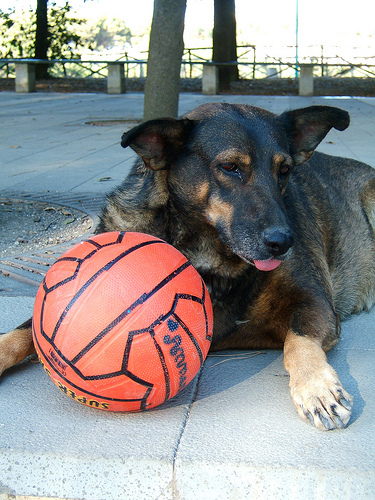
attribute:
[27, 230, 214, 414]
ball — orange, black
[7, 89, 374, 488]
ground — concrete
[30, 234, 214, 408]
lines — black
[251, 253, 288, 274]
tongue — pink, out, sticking out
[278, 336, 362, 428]
dog — laying, brownish, dark, lying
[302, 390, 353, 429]
nails — grey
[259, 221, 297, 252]
nose — black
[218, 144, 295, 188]
eyes — open, brown, dog's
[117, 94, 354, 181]
ears — dog's, wagging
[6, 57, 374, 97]
benches — green, concrete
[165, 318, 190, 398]
writing — blue, black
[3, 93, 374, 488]
concrete — white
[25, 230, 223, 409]
football — red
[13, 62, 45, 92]
pillar — stone, short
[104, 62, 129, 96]
pillar — stone, short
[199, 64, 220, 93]
pillar — stone, short